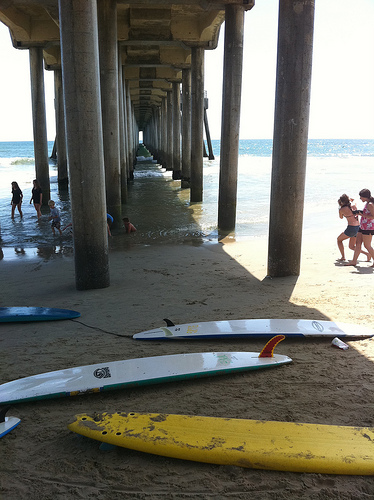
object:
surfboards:
[0, 306, 374, 474]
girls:
[337, 188, 374, 267]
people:
[10, 179, 136, 236]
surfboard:
[0, 335, 293, 404]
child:
[48, 200, 62, 236]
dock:
[0, 0, 316, 291]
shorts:
[344, 225, 359, 237]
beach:
[0, 143, 374, 498]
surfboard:
[133, 317, 372, 338]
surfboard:
[0, 306, 82, 322]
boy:
[121, 218, 137, 233]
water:
[0, 139, 374, 261]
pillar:
[267, 1, 315, 276]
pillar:
[58, 0, 110, 290]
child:
[337, 193, 371, 261]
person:
[11, 181, 23, 218]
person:
[30, 180, 42, 218]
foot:
[338, 256, 345, 260]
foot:
[344, 260, 356, 266]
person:
[344, 189, 374, 268]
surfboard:
[67, 411, 374, 474]